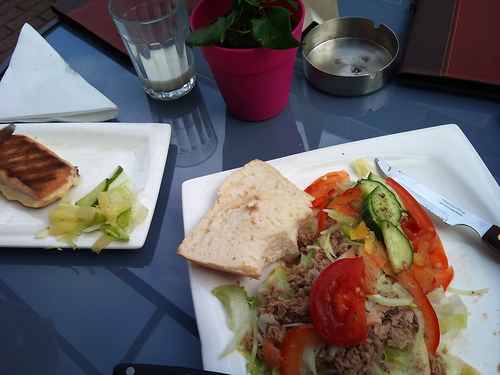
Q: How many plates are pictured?
A: Two.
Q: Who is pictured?
A: No one.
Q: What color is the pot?
A: Red.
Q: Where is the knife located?
A: On plate.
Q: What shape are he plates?
A: Square.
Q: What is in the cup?
A: Milk.